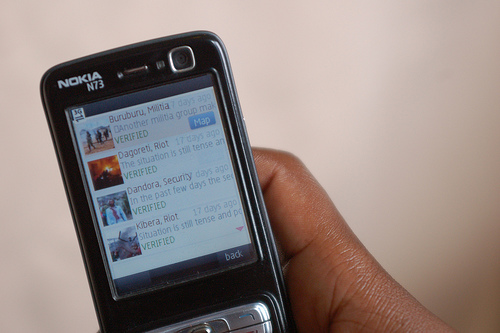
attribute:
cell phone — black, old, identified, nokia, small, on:
[37, 31, 277, 333]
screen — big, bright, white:
[85, 92, 252, 273]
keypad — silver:
[164, 302, 277, 332]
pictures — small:
[77, 125, 146, 265]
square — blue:
[186, 112, 218, 129]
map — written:
[188, 112, 217, 130]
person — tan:
[263, 134, 401, 332]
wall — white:
[254, 2, 495, 142]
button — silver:
[225, 304, 268, 325]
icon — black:
[225, 247, 249, 266]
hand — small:
[270, 157, 424, 332]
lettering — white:
[195, 117, 210, 127]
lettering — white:
[222, 251, 246, 260]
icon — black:
[115, 271, 148, 299]